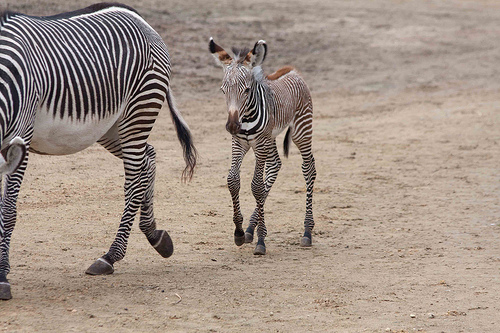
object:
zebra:
[0, 3, 197, 303]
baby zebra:
[207, 33, 320, 257]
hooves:
[229, 232, 313, 258]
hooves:
[2, 230, 180, 303]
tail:
[163, 85, 199, 185]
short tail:
[281, 126, 293, 160]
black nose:
[224, 120, 247, 136]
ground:
[2, 2, 499, 332]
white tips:
[207, 35, 270, 45]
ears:
[205, 36, 269, 66]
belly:
[29, 107, 129, 157]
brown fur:
[265, 65, 293, 81]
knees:
[225, 171, 269, 200]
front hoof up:
[229, 227, 248, 247]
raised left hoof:
[151, 229, 175, 258]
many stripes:
[217, 64, 315, 235]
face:
[217, 66, 261, 135]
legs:
[1, 154, 174, 282]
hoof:
[85, 257, 115, 278]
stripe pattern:
[6, 12, 158, 267]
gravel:
[0, 126, 498, 329]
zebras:
[0, 2, 323, 308]